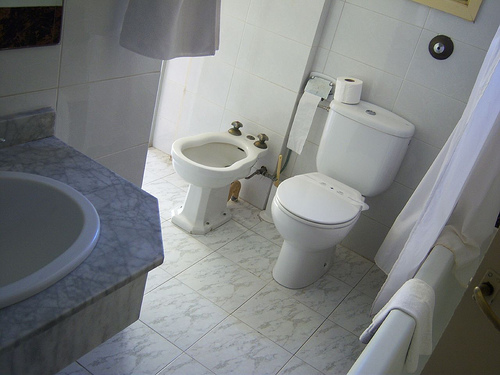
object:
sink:
[0, 169, 101, 307]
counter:
[0, 135, 163, 353]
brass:
[251, 134, 271, 153]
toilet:
[170, 120, 271, 236]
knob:
[227, 121, 243, 137]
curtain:
[365, 28, 499, 317]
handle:
[466, 281, 500, 331]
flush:
[362, 108, 378, 116]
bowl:
[274, 170, 366, 227]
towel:
[116, 0, 222, 62]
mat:
[355, 278, 435, 374]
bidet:
[167, 121, 268, 236]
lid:
[274, 172, 365, 226]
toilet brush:
[273, 155, 285, 188]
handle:
[270, 155, 283, 183]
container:
[256, 180, 284, 224]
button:
[363, 107, 379, 117]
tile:
[229, 283, 326, 357]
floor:
[55, 145, 397, 374]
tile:
[172, 248, 274, 314]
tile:
[76, 317, 185, 375]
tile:
[291, 317, 368, 374]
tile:
[210, 229, 285, 282]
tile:
[136, 175, 196, 222]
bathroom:
[204, 0, 499, 144]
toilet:
[271, 97, 416, 289]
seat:
[270, 171, 366, 229]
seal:
[273, 170, 368, 227]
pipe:
[275, 148, 290, 175]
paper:
[330, 77, 364, 105]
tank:
[313, 100, 414, 199]